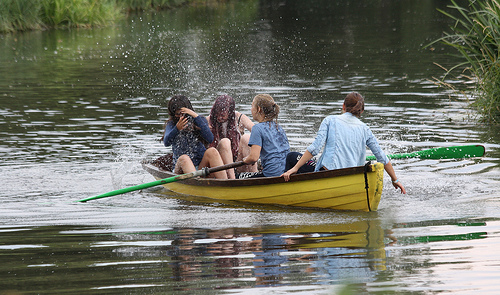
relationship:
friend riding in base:
[280, 92, 406, 195] [140, 162, 383, 213]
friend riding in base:
[236, 94, 291, 180] [140, 162, 383, 213]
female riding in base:
[163, 95, 228, 179] [140, 162, 383, 213]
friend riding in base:
[205, 94, 259, 179] [140, 162, 383, 213]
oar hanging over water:
[76, 161, 245, 203] [151, 192, 413, 243]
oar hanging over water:
[365, 144, 486, 162] [151, 192, 413, 243]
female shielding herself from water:
[163, 95, 228, 179] [122, 173, 469, 241]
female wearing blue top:
[161, 95, 226, 179] [163, 115, 214, 171]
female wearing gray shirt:
[163, 95, 228, 179] [248, 121, 290, 177]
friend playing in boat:
[288, 83, 405, 207] [126, 147, 399, 226]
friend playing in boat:
[231, 89, 291, 184] [126, 147, 399, 226]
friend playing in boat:
[203, 82, 255, 186] [126, 147, 399, 226]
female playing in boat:
[163, 95, 228, 179] [126, 147, 399, 226]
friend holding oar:
[236, 94, 291, 180] [76, 155, 263, 212]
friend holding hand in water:
[280, 92, 406, 195] [1, 0, 499, 293]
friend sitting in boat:
[280, 92, 406, 195] [141, 149, 383, 210]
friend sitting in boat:
[236, 94, 291, 180] [141, 149, 383, 210]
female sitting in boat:
[163, 95, 228, 179] [141, 149, 383, 210]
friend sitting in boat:
[205, 94, 259, 179] [141, 149, 383, 210]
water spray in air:
[10, 11, 479, 168] [0, 1, 500, 182]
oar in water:
[76, 155, 263, 212] [1, 0, 499, 293]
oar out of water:
[366, 142, 486, 159] [1, 0, 499, 293]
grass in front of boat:
[0, 0, 500, 143] [141, 149, 383, 210]